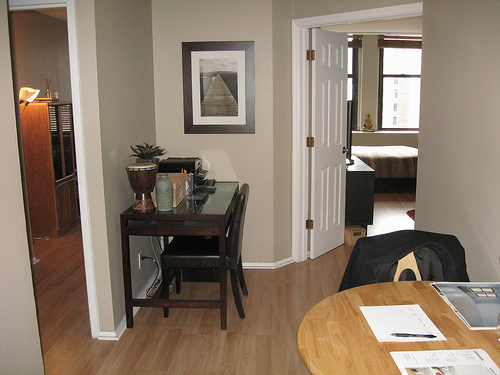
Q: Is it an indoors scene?
A: Yes, it is indoors.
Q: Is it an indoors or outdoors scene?
A: It is indoors.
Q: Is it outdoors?
A: No, it is indoors.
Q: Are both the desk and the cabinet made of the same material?
A: Yes, both the desk and the cabinet are made of wood.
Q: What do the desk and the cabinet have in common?
A: The material, both the desk and the cabinet are wooden.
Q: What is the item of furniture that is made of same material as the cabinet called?
A: The piece of furniture is a desk.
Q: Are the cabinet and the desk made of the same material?
A: Yes, both the cabinet and the desk are made of wood.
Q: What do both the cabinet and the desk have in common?
A: The material, both the cabinet and the desk are wooden.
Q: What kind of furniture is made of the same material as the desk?
A: The cabinet is made of the same material as the desk.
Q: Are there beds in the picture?
A: Yes, there is a bed.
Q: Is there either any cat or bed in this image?
A: Yes, there is a bed.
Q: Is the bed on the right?
A: Yes, the bed is on the right of the image.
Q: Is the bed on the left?
A: No, the bed is on the right of the image.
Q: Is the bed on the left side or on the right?
A: The bed is on the right of the image.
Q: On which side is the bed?
A: The bed is on the right of the image.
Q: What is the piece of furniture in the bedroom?
A: The piece of furniture is a bed.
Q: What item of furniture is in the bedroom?
A: The piece of furniture is a bed.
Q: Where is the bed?
A: The bed is in the bedroom.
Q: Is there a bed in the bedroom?
A: Yes, there is a bed in the bedroom.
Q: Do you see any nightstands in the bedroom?
A: No, there is a bed in the bedroom.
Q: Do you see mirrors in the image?
A: No, there are no mirrors.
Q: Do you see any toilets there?
A: No, there are no toilets.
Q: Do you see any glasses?
A: No, there are no glasses.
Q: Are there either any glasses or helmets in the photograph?
A: No, there are no glasses or helmets.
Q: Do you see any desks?
A: Yes, there is a desk.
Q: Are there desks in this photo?
A: Yes, there is a desk.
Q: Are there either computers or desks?
A: Yes, there is a desk.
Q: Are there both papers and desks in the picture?
A: Yes, there are both a desk and papers.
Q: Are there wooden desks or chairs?
A: Yes, there is a wood desk.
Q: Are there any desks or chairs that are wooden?
A: Yes, the desk is wooden.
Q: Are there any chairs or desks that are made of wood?
A: Yes, the desk is made of wood.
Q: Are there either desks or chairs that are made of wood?
A: Yes, the desk is made of wood.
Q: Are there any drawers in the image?
A: No, there are no drawers.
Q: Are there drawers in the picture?
A: No, there are no drawers.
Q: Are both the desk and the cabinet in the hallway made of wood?
A: Yes, both the desk and the cabinet are made of wood.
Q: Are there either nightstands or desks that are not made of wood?
A: No, there is a desk but it is made of wood.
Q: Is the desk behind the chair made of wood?
A: Yes, the desk is made of wood.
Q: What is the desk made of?
A: The desk is made of wood.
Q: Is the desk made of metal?
A: No, the desk is made of wood.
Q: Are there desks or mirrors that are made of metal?
A: No, there is a desk but it is made of wood.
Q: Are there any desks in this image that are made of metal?
A: No, there is a desk but it is made of wood.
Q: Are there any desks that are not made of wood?
A: No, there is a desk but it is made of wood.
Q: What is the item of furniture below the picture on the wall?
A: The piece of furniture is a desk.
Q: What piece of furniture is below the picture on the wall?
A: The piece of furniture is a desk.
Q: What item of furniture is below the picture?
A: The piece of furniture is a desk.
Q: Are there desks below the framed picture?
A: Yes, there is a desk below the picture.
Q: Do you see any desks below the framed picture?
A: Yes, there is a desk below the picture.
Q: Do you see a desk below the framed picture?
A: Yes, there is a desk below the picture.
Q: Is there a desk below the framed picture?
A: Yes, there is a desk below the picture.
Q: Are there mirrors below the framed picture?
A: No, there is a desk below the picture.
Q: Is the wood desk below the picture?
A: Yes, the desk is below the picture.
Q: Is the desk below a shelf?
A: No, the desk is below the picture.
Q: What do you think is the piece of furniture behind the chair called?
A: The piece of furniture is a desk.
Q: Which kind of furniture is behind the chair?
A: The piece of furniture is a desk.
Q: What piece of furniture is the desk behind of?
A: The desk is behind the chair.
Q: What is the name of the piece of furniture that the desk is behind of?
A: The piece of furniture is a chair.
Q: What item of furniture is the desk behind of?
A: The desk is behind the chair.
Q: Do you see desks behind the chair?
A: Yes, there is a desk behind the chair.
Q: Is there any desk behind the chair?
A: Yes, there is a desk behind the chair.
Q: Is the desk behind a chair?
A: Yes, the desk is behind a chair.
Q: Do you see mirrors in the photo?
A: No, there are no mirrors.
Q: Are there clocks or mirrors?
A: No, there are no mirrors or clocks.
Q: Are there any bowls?
A: No, there are no bowls.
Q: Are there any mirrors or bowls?
A: No, there are no bowls or mirrors.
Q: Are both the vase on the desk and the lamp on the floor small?
A: Yes, both the vase and the lamp are small.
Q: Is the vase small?
A: Yes, the vase is small.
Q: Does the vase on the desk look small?
A: Yes, the vase is small.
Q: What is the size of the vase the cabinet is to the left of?
A: The vase is small.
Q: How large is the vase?
A: The vase is small.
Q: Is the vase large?
A: No, the vase is small.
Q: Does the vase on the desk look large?
A: No, the vase is small.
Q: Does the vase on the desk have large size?
A: No, the vase is small.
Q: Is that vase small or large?
A: The vase is small.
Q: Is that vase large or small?
A: The vase is small.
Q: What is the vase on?
A: The vase is on the desk.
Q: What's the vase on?
A: The vase is on the desk.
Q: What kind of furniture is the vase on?
A: The vase is on the desk.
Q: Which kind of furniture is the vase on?
A: The vase is on the desk.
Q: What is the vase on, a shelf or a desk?
A: The vase is on a desk.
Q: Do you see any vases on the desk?
A: Yes, there is a vase on the desk.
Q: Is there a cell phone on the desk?
A: No, there is a vase on the desk.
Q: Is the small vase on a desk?
A: Yes, the vase is on a desk.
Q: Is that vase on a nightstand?
A: No, the vase is on a desk.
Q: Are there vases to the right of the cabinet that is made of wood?
A: Yes, there is a vase to the right of the cabinet.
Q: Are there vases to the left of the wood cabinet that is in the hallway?
A: No, the vase is to the right of the cabinet.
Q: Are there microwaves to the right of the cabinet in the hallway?
A: No, there is a vase to the right of the cabinet.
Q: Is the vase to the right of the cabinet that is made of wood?
A: Yes, the vase is to the right of the cabinet.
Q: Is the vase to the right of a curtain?
A: No, the vase is to the right of the cabinet.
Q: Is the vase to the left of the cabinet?
A: No, the vase is to the right of the cabinet.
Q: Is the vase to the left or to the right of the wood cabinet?
A: The vase is to the right of the cabinet.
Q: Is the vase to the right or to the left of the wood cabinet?
A: The vase is to the right of the cabinet.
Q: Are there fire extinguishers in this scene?
A: No, there are no fire extinguishers.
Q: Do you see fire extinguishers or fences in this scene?
A: No, there are no fire extinguishers or fences.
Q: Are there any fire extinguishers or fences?
A: No, there are no fire extinguishers or fences.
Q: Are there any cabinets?
A: Yes, there is a cabinet.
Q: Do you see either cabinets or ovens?
A: Yes, there is a cabinet.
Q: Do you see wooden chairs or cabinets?
A: Yes, there is a wood cabinet.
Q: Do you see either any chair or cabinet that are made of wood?
A: Yes, the cabinet is made of wood.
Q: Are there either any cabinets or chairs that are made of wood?
A: Yes, the cabinet is made of wood.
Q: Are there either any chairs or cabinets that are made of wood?
A: Yes, the cabinet is made of wood.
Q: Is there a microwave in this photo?
A: No, there are no microwaves.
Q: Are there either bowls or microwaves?
A: No, there are no microwaves or bowls.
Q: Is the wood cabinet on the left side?
A: Yes, the cabinet is on the left of the image.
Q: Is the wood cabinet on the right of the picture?
A: No, the cabinet is on the left of the image.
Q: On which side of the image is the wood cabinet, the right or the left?
A: The cabinet is on the left of the image.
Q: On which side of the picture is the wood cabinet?
A: The cabinet is on the left of the image.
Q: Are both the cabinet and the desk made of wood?
A: Yes, both the cabinet and the desk are made of wood.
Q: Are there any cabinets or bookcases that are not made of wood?
A: No, there is a cabinet but it is made of wood.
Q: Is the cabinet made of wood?
A: Yes, the cabinet is made of wood.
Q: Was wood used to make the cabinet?
A: Yes, the cabinet is made of wood.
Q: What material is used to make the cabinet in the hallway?
A: The cabinet is made of wood.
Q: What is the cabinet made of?
A: The cabinet is made of wood.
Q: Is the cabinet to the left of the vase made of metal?
A: No, the cabinet is made of wood.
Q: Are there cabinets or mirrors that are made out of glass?
A: No, there is a cabinet but it is made of wood.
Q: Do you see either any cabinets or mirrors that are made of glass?
A: No, there is a cabinet but it is made of wood.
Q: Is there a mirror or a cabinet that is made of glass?
A: No, there is a cabinet but it is made of wood.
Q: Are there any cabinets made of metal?
A: No, there is a cabinet but it is made of wood.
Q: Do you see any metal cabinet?
A: No, there is a cabinet but it is made of wood.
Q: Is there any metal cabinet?
A: No, there is a cabinet but it is made of wood.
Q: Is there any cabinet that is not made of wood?
A: No, there is a cabinet but it is made of wood.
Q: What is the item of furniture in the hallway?
A: The piece of furniture is a cabinet.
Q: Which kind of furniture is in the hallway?
A: The piece of furniture is a cabinet.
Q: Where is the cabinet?
A: The cabinet is in the hallway.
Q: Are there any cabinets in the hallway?
A: Yes, there is a cabinet in the hallway.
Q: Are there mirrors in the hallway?
A: No, there is a cabinet in the hallway.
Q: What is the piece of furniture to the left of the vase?
A: The piece of furniture is a cabinet.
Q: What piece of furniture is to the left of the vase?
A: The piece of furniture is a cabinet.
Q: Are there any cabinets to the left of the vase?
A: Yes, there is a cabinet to the left of the vase.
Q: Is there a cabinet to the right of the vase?
A: No, the cabinet is to the left of the vase.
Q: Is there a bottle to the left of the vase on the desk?
A: No, there is a cabinet to the left of the vase.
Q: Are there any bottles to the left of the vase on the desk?
A: No, there is a cabinet to the left of the vase.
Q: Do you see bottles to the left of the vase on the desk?
A: No, there is a cabinet to the left of the vase.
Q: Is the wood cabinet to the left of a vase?
A: Yes, the cabinet is to the left of a vase.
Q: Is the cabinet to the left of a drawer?
A: No, the cabinet is to the left of a vase.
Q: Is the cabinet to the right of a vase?
A: No, the cabinet is to the left of a vase.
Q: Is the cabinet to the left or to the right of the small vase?
A: The cabinet is to the left of the vase.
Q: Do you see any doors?
A: Yes, there is a door.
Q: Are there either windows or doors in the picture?
A: Yes, there is a door.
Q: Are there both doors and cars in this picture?
A: No, there is a door but no cars.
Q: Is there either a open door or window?
A: Yes, there is an open door.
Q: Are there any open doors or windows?
A: Yes, there is an open door.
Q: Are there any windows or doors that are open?
A: Yes, the door is open.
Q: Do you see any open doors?
A: Yes, there is an open door.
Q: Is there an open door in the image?
A: Yes, there is an open door.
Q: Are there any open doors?
A: Yes, there is an open door.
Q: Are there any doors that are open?
A: Yes, there is a door that is open.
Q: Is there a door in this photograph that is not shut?
A: Yes, there is a open door.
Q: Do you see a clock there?
A: No, there are no clocks.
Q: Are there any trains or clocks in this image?
A: No, there are no clocks or trains.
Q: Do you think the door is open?
A: Yes, the door is open.